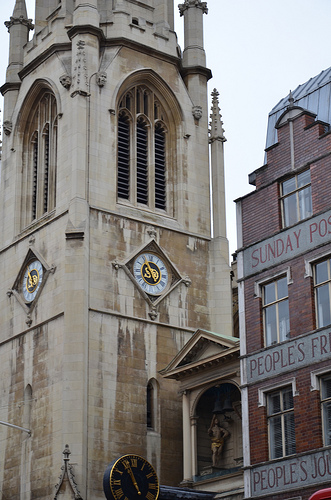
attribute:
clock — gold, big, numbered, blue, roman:
[125, 250, 183, 308]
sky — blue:
[203, 4, 330, 270]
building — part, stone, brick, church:
[236, 59, 329, 498]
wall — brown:
[294, 372, 321, 446]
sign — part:
[243, 448, 330, 500]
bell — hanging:
[204, 390, 247, 418]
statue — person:
[201, 418, 235, 469]